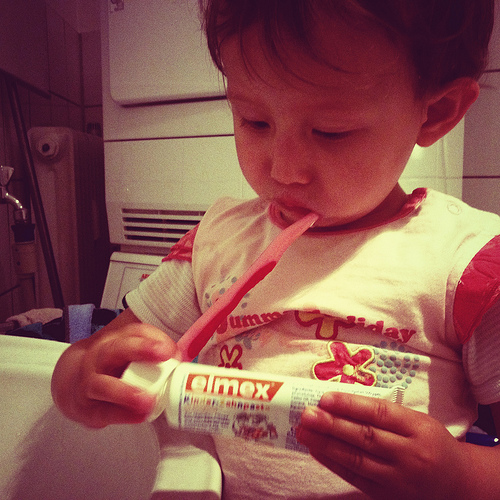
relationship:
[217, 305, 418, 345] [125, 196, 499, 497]
writing on shirt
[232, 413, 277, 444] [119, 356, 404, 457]
drawing on toothpaste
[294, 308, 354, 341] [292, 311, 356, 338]
flower has border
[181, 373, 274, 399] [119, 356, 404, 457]
writing on toothpaste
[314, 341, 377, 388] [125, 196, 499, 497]
flower on shirt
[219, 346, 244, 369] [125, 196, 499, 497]
flower on shirt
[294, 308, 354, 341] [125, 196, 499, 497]
flower on shirt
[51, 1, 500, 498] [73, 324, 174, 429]
child has hand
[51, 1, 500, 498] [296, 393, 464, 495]
child has hand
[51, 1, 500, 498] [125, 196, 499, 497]
child has shirt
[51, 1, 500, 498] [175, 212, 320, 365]
child with toothbrush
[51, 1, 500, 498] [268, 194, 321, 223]
child has mouth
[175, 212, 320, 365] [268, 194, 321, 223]
toothbrush sticking out of mouth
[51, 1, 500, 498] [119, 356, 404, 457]
child holding toothpaste